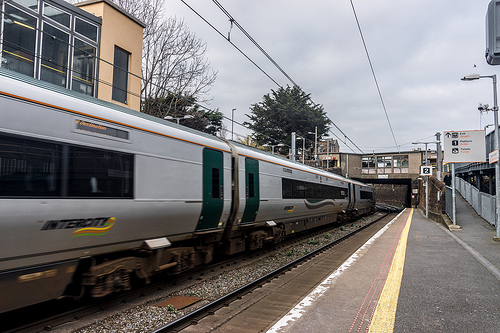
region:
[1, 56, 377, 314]
a pretty grey train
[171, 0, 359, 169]
electrical wires above the train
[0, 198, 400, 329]
metal train rails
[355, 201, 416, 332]
a yellow safety line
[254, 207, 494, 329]
empty train platform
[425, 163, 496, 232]
entrance ramp to the platform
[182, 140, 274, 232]
two green train doors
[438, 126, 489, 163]
a white sign directing transfers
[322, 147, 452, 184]
a covered bridge over the train tracks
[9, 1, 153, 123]
a building with large windows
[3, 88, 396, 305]
Gray colored train is on the train tracks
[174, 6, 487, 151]
The sky is cloudy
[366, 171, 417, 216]
Small train tunnel is in the background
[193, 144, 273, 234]
Train has green colored doors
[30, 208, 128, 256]
Train has words written on its side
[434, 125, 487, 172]
White sign is in the background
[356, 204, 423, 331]
A yellow line is by the train tracks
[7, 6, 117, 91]
Windows to a building is on top of train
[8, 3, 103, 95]
Windows have a gray and white outline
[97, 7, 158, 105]
Building on top of train is tan colored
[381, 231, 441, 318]
Yellow line on cement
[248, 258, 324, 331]
Train track by a train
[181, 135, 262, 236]
Green doors on a train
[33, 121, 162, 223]
Window on a train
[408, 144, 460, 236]
Sign by a train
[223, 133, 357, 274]
Silver train car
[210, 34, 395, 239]
Power lines over a train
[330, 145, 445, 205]
Bridge over train tracks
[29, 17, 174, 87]
Building by a train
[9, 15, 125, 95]
Windows on a building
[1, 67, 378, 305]
long commuter passenger train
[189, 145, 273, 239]
Green train doors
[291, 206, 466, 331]
Cement train platform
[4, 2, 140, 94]
windows overlooking commuter train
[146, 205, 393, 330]
old empty railroad track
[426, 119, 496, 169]
Street sign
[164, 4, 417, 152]
power lines hanging over train tracks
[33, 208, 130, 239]
intercity sign on side of commuter train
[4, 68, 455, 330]
A train is parked at a train station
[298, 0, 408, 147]
a hanging wire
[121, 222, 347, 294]
the train tracks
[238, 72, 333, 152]
a big bushy tree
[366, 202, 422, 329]
a long yellow stripe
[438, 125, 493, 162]
a sign with directions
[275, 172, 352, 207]
a long train window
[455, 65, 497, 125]
a tall light pole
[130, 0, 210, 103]
a tall bare tree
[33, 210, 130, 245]
the name or type of train